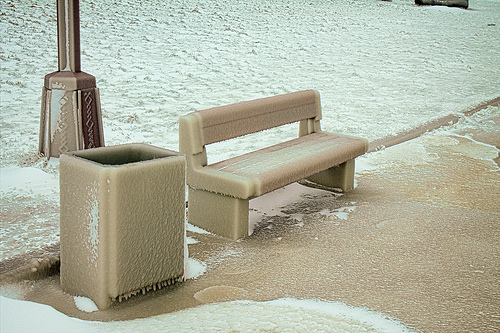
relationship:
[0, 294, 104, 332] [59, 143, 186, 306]
snow next to trash can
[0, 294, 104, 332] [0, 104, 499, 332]
snow on sidewalk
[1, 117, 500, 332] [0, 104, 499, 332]
ice on sidewalk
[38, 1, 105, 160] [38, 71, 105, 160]
light has base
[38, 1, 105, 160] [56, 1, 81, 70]
light has post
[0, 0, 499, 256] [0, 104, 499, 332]
snow behind sidewalk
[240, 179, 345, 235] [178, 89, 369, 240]
snow under bench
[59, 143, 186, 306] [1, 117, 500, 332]
trash can covered in ice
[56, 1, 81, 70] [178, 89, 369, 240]
post behind bench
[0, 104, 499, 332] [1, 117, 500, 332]
sidewalk covered in ice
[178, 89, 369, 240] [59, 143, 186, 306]
bench next to trash can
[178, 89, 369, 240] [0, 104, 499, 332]
bench on sidewalk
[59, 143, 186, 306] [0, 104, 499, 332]
trash can on sidewalk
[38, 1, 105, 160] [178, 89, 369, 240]
light behind bench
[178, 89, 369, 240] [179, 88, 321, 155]
bench has top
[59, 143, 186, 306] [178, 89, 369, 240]
trash can next to bench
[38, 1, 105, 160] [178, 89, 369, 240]
light next to bench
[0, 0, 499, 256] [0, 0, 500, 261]
snow on top of grass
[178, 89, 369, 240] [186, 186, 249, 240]
bench has leg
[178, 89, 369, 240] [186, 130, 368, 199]
bench has seat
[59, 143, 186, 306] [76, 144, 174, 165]
trash can has mouth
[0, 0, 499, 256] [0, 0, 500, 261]
snow on grass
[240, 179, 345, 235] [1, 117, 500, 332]
snow on ice